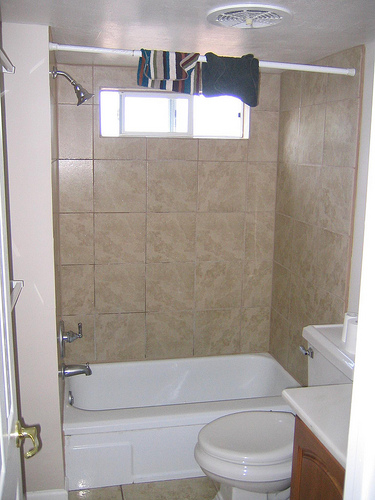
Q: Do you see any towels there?
A: Yes, there is a towel.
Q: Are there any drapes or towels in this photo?
A: Yes, there is a towel.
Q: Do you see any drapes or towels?
A: Yes, there is a towel.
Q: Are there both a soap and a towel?
A: No, there is a towel but no soaps.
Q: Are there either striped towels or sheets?
A: Yes, there is a striped towel.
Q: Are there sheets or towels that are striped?
A: Yes, the towel is striped.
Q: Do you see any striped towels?
A: Yes, there is a striped towel.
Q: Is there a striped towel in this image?
A: Yes, there is a striped towel.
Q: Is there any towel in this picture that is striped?
A: Yes, there is a towel that is striped.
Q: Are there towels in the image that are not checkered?
A: Yes, there is a striped towel.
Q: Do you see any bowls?
A: No, there are no bowls.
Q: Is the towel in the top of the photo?
A: Yes, the towel is in the top of the image.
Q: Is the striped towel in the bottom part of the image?
A: No, the towel is in the top of the image.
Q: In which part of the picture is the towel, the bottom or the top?
A: The towel is in the top of the image.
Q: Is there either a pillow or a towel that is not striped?
A: No, there is a towel but it is striped.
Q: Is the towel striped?
A: Yes, the towel is striped.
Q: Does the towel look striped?
A: Yes, the towel is striped.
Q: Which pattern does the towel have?
A: The towel has striped pattern.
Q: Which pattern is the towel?
A: The towel is striped.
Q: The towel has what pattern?
A: The towel is striped.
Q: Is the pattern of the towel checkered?
A: No, the towel is striped.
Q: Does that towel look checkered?
A: No, the towel is striped.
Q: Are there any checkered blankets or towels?
A: No, there is a towel but it is striped.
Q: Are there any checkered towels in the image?
A: No, there is a towel but it is striped.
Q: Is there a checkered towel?
A: No, there is a towel but it is striped.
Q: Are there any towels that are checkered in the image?
A: No, there is a towel but it is striped.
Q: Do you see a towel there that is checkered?
A: No, there is a towel but it is striped.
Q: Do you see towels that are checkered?
A: No, there is a towel but it is striped.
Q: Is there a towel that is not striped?
A: No, there is a towel but it is striped.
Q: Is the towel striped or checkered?
A: The towel is striped.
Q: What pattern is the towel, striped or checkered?
A: The towel is striped.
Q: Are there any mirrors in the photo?
A: No, there are no mirrors.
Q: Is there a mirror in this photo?
A: No, there are no mirrors.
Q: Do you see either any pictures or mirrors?
A: No, there are no mirrors or pictures.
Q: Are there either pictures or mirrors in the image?
A: No, there are no mirrors or pictures.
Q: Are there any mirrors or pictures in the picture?
A: No, there are no mirrors or pictures.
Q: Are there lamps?
A: No, there are no lamps.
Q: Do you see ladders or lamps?
A: No, there are no lamps or ladders.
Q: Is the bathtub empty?
A: Yes, the bathtub is empty.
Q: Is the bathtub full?
A: No, the bathtub is empty.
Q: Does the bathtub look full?
A: No, the bathtub is empty.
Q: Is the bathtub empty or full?
A: The bathtub is empty.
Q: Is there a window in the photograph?
A: Yes, there is a window.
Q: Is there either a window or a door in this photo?
A: Yes, there is a window.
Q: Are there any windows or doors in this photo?
A: Yes, there is a window.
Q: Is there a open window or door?
A: Yes, there is an open window.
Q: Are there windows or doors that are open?
A: Yes, the window is open.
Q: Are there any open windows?
A: Yes, there is an open window.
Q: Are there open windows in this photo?
A: Yes, there is an open window.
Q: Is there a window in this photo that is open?
A: Yes, there is a window that is open.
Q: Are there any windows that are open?
A: Yes, there is a window that is open.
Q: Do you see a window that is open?
A: Yes, there is a window that is open.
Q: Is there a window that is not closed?
A: Yes, there is a open window.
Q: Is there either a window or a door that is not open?
A: No, there is a window but it is open.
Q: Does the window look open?
A: Yes, the window is open.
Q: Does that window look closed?
A: No, the window is open.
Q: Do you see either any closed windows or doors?
A: No, there is a window but it is open.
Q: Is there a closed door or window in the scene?
A: No, there is a window but it is open.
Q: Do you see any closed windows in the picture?
A: No, there is a window but it is open.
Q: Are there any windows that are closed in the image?
A: No, there is a window but it is open.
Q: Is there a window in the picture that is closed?
A: No, there is a window but it is open.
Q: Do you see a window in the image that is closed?
A: No, there is a window but it is open.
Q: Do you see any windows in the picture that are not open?
A: No, there is a window but it is open.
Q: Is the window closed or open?
A: The window is open.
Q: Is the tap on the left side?
A: Yes, the tap is on the left of the image.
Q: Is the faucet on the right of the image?
A: No, the faucet is on the left of the image.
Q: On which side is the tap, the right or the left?
A: The tap is on the left of the image.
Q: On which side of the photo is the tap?
A: The tap is on the left of the image.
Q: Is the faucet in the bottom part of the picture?
A: Yes, the faucet is in the bottom of the image.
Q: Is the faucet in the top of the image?
A: No, the faucet is in the bottom of the image.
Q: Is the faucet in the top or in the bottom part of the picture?
A: The faucet is in the bottom of the image.